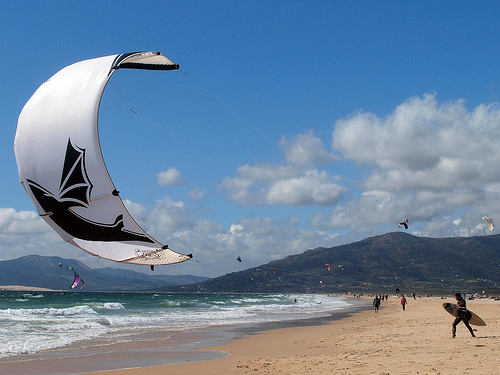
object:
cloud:
[245, 94, 498, 233]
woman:
[397, 294, 410, 311]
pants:
[399, 301, 405, 311]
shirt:
[399, 298, 408, 305]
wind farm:
[415, 227, 499, 239]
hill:
[196, 226, 499, 291]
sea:
[0, 281, 350, 370]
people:
[339, 278, 495, 339]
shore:
[117, 287, 500, 374]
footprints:
[265, 336, 469, 373]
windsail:
[62, 264, 85, 294]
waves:
[7, 304, 143, 351]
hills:
[0, 230, 499, 297]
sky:
[0, 0, 500, 250]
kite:
[14, 52, 192, 270]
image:
[23, 143, 156, 250]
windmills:
[408, 221, 500, 238]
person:
[443, 286, 483, 345]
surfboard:
[440, 301, 487, 329]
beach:
[4, 1, 495, 374]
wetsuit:
[453, 301, 473, 320]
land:
[0, 222, 499, 372]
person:
[395, 292, 412, 310]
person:
[369, 292, 383, 314]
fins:
[49, 136, 95, 204]